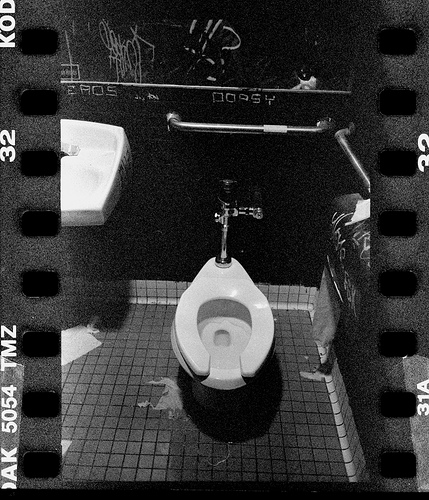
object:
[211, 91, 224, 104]
d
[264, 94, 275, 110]
letter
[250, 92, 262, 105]
letter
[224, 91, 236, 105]
letter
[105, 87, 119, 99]
letter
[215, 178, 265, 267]
pipe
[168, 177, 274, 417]
toilet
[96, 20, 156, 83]
graffiti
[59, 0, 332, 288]
wall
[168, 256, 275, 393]
toilet bowl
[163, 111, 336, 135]
handle bars.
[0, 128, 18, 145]
number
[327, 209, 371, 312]
graffiti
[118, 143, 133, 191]
graffiti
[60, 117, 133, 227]
sink